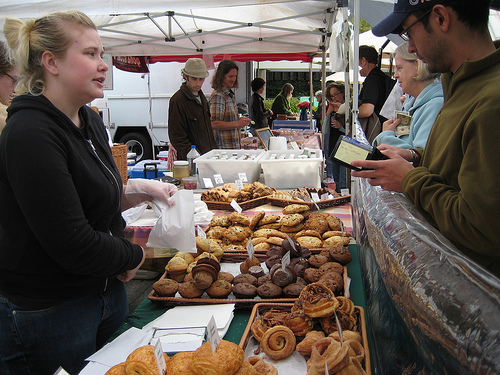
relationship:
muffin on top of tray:
[152, 278, 179, 296] [148, 250, 348, 303]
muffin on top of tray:
[166, 257, 187, 280] [148, 250, 348, 303]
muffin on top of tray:
[175, 250, 194, 262] [148, 250, 348, 303]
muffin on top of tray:
[178, 279, 203, 297] [148, 250, 348, 303]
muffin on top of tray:
[192, 263, 218, 286] [148, 250, 348, 303]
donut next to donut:
[262, 327, 296, 361] [251, 315, 281, 340]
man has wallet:
[350, 1, 499, 268] [329, 133, 390, 179]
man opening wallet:
[350, 1, 499, 268] [329, 133, 390, 179]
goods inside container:
[207, 149, 258, 160] [193, 145, 264, 184]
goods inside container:
[268, 147, 317, 159] [259, 148, 324, 188]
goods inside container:
[183, 182, 198, 189] [182, 177, 198, 189]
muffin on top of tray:
[271, 264, 297, 287] [148, 250, 348, 303]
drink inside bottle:
[187, 156, 198, 175] [185, 145, 201, 176]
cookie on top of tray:
[224, 226, 247, 243] [197, 219, 348, 255]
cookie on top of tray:
[224, 243, 246, 252] [197, 219, 348, 255]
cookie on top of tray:
[229, 211, 251, 226] [197, 219, 348, 255]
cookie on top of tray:
[205, 225, 226, 239] [197, 219, 348, 255]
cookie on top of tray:
[209, 216, 231, 228] [197, 219, 348, 255]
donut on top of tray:
[343, 338, 364, 359] [237, 300, 373, 375]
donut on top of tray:
[297, 329, 324, 350] [237, 300, 373, 375]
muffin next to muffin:
[239, 256, 260, 272] [248, 264, 264, 277]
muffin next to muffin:
[216, 269, 233, 282] [206, 278, 232, 296]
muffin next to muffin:
[265, 245, 284, 254] [265, 254, 283, 266]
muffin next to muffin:
[281, 236, 302, 257] [298, 244, 311, 257]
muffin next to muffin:
[291, 257, 307, 276] [284, 279, 307, 296]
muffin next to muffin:
[195, 255, 223, 270] [192, 263, 218, 286]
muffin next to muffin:
[295, 275, 308, 286] [284, 279, 307, 296]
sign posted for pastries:
[310, 192, 321, 204] [271, 188, 313, 203]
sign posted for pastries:
[321, 192, 330, 203] [290, 187, 314, 199]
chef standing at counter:
[1, 10, 146, 350] [78, 235, 376, 373]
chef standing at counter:
[165, 57, 217, 160] [239, 125, 326, 174]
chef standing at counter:
[209, 59, 250, 148] [239, 125, 326, 174]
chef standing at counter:
[251, 75, 272, 127] [290, 109, 313, 125]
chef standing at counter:
[270, 82, 295, 119] [290, 109, 313, 125]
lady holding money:
[372, 42, 445, 150] [393, 111, 412, 139]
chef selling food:
[1, 10, 146, 350] [145, 190, 201, 254]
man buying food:
[350, 1, 499, 268] [145, 190, 201, 254]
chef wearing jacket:
[1, 10, 146, 350] [0, 92, 144, 301]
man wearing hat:
[350, 1, 499, 268] [370, 0, 443, 37]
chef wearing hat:
[165, 57, 217, 160] [181, 57, 211, 79]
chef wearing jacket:
[165, 57, 217, 160] [166, 83, 217, 160]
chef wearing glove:
[1, 10, 146, 350] [124, 176, 177, 204]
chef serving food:
[1, 10, 146, 350] [145, 190, 201, 254]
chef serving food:
[209, 59, 250, 148] [249, 116, 257, 125]